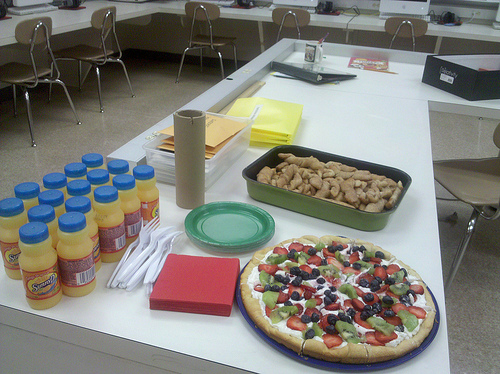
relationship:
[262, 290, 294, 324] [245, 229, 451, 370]
kiwi on slices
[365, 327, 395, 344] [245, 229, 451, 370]
strawberries on slices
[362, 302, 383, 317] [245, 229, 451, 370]
blueberries on slices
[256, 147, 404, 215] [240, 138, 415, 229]
chicken in dish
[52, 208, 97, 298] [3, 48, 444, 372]
bottle on table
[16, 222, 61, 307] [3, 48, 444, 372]
bottle on table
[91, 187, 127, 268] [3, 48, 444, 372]
bottle on table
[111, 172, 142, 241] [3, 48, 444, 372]
bottle on table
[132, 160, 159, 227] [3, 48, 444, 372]
bottle on table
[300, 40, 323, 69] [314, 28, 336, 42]
white mug holding pens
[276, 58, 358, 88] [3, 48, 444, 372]
ring folder on table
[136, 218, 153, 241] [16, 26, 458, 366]
fork laying table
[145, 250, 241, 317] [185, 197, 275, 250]
napkins next to plates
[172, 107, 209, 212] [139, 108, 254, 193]
tube by bin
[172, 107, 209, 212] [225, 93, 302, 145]
tube by folders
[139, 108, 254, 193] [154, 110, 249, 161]
bin of envelopes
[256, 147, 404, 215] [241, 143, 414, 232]
chicken on dish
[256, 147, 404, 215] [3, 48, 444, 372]
chicken on table